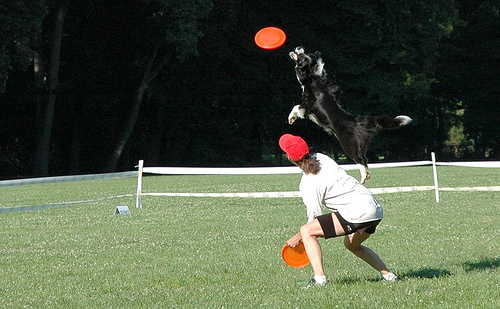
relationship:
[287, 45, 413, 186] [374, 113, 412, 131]
dog has tail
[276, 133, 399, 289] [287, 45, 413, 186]
person with dog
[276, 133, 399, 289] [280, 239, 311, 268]
person holding frisbee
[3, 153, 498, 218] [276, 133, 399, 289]
fence behind person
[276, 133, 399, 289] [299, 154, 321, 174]
person has hair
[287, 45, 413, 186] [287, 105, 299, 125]
dog has paw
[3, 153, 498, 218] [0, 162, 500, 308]
fence in field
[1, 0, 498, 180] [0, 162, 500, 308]
trees at  end of field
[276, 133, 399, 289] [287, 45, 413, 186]
woman playing with dog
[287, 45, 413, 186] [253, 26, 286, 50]
dog reaching for frisbee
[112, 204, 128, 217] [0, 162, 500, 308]
paper on ground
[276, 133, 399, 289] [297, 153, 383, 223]
woman wearing thsirt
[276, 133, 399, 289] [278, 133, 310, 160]
woman wears hat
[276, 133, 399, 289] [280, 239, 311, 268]
woman has frisbee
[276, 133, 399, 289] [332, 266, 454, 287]
woman has shadow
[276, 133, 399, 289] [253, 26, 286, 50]
woman throw frisbee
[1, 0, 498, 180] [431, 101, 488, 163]
trees have path